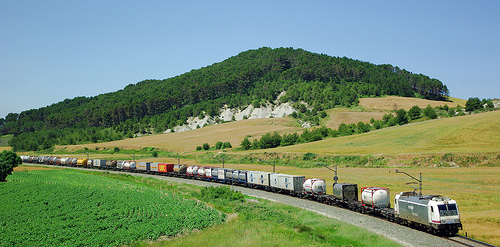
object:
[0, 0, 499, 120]
sky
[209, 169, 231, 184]
car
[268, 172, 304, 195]
cargo car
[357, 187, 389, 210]
car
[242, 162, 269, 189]
cargo car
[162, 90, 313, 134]
rocky area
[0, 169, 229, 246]
foliage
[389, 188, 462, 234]
locomotive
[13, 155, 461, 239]
train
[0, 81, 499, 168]
hillside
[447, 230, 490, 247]
track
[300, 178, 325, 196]
tanker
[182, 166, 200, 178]
tanker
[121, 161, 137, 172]
tanker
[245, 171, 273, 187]
car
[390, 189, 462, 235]
engine car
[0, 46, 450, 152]
trees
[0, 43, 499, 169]
hill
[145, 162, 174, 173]
freight car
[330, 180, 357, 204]
cargo cars